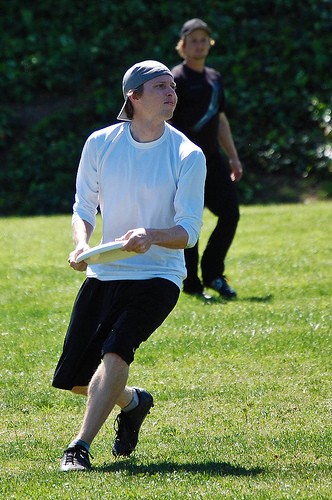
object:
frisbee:
[76, 240, 138, 265]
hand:
[115, 227, 152, 253]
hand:
[68, 243, 91, 271]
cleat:
[112, 387, 154, 455]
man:
[52, 59, 207, 472]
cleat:
[60, 444, 94, 475]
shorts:
[52, 277, 180, 389]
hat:
[116, 59, 173, 122]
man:
[167, 18, 243, 298]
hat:
[182, 18, 213, 36]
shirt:
[74, 119, 207, 291]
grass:
[2, 202, 331, 500]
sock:
[122, 389, 139, 413]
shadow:
[91, 459, 263, 477]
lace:
[113, 413, 120, 432]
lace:
[87, 451, 94, 459]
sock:
[70, 439, 89, 451]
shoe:
[210, 274, 236, 296]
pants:
[182, 157, 240, 292]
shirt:
[168, 62, 227, 152]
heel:
[135, 389, 154, 408]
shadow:
[207, 293, 271, 304]